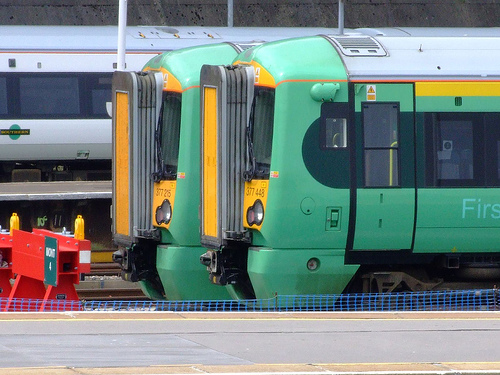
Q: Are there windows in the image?
A: Yes, there is a window.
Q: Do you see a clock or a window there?
A: Yes, there is a window.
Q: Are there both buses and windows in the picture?
A: No, there is a window but no buses.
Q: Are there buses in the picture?
A: No, there are no buses.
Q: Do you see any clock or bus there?
A: No, there are no buses or clocks.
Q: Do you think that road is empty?
A: Yes, the road is empty.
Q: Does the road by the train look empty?
A: Yes, the road is empty.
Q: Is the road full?
A: No, the road is empty.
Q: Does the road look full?
A: No, the road is empty.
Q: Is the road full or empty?
A: The road is empty.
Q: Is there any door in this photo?
A: Yes, there is a door.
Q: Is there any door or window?
A: Yes, there is a door.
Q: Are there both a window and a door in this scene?
A: Yes, there are both a door and a window.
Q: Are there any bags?
A: No, there are no bags.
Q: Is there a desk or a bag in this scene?
A: No, there are no bags or desks.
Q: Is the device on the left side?
A: Yes, the device is on the left of the image.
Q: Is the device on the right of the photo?
A: No, the device is on the left of the image.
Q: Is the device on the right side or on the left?
A: The device is on the left of the image.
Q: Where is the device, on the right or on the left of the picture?
A: The device is on the left of the image.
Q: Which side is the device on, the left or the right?
A: The device is on the left of the image.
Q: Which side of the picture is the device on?
A: The device is on the left of the image.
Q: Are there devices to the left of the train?
A: Yes, there is a device to the left of the train.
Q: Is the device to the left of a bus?
A: No, the device is to the left of the train.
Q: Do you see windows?
A: Yes, there is a window.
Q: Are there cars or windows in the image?
A: Yes, there is a window.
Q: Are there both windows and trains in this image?
A: Yes, there are both a window and a train.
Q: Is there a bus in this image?
A: No, there are no buses.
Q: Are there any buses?
A: No, there are no buses.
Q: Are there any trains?
A: Yes, there is a train.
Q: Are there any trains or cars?
A: Yes, there is a train.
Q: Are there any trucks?
A: No, there are no trucks.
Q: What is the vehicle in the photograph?
A: The vehicle is a train.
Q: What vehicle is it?
A: The vehicle is a train.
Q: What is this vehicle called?
A: This is a train.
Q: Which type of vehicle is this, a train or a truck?
A: This is a train.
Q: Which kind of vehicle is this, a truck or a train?
A: This is a train.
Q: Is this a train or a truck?
A: This is a train.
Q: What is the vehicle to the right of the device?
A: The vehicle is a train.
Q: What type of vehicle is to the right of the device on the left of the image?
A: The vehicle is a train.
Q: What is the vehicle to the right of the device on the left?
A: The vehicle is a train.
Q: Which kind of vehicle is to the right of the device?
A: The vehicle is a train.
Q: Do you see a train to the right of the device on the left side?
A: Yes, there is a train to the right of the device.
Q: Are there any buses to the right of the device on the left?
A: No, there is a train to the right of the device.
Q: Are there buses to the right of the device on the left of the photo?
A: No, there is a train to the right of the device.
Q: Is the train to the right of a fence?
A: No, the train is to the right of a device.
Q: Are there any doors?
A: Yes, there is a door.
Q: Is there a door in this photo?
A: Yes, there is a door.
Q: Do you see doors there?
A: Yes, there is a door.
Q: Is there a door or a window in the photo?
A: Yes, there is a door.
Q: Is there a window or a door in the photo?
A: Yes, there is a door.